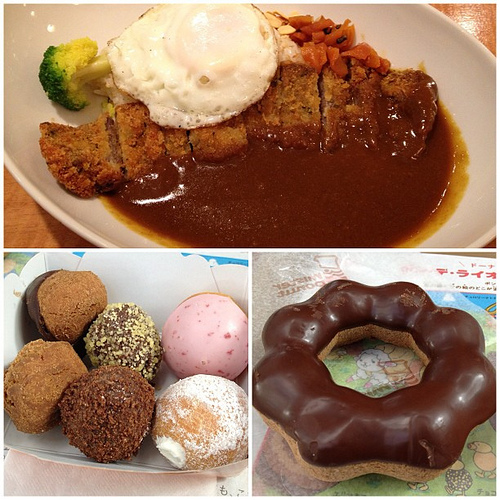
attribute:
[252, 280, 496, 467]
frosting — brown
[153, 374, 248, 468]
topping — powdered sugar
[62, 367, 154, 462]
coconut — brown, chocolate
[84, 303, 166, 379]
almond — chopped, yellow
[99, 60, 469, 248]
gravy — brown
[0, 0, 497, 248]
plate — white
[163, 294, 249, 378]
icing — pink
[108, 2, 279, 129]
potatoes — mashed, fried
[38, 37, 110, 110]
broccoli — green, yellow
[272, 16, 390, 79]
carrots — chopped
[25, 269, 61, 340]
icing — chocolate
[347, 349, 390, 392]
bunny — white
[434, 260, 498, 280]
writing — red